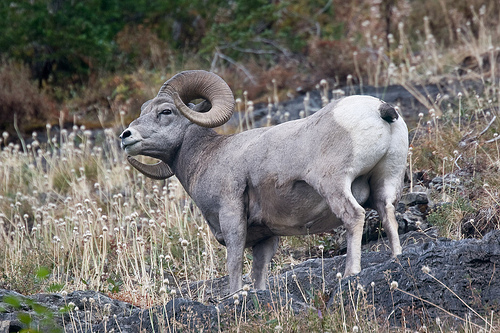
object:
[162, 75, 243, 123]
horn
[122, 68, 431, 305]
ram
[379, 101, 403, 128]
tail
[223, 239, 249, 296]
front leg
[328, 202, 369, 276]
rear leg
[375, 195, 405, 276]
rear leg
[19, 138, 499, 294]
field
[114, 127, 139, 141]
nose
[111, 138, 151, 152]
mouth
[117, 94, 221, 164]
head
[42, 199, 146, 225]
buds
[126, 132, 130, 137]
nostril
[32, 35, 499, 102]
grass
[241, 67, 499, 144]
terrain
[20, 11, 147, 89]
bush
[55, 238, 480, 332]
weed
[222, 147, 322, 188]
coat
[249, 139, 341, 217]
body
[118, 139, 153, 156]
muzzle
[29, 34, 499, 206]
hillside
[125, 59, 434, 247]
sheep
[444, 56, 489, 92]
rock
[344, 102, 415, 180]
rump